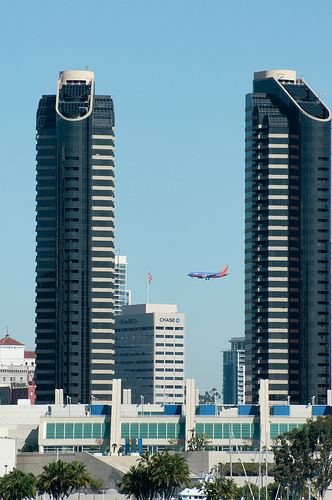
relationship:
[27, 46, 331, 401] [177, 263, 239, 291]
buildings near plane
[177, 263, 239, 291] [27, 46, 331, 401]
plane near buildings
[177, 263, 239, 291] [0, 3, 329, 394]
plane in sky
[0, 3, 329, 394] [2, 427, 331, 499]
sky above trees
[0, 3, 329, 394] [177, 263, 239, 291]
sky above plane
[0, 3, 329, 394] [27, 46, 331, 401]
sky above buildings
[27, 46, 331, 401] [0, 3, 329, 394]
buildings below sky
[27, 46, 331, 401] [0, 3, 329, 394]
buildings under sky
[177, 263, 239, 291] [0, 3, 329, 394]
plane under sky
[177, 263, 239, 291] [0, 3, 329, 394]
plane below sky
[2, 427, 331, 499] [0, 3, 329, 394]
trees below sky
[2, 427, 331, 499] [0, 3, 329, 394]
trees under sky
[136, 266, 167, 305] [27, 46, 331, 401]
flag on buildings